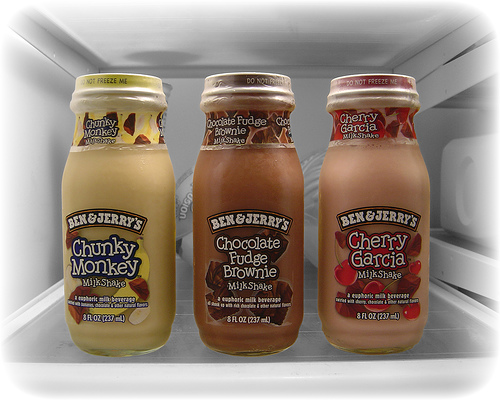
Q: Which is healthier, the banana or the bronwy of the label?
A: The banana is healthier than the brownie.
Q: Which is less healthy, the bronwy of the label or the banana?
A: The brownie is less healthy than the banana.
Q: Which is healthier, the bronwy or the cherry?
A: The cherry is healthier than the bronwy.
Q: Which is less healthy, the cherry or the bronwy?
A: The bronwy is less healthy than the cherry.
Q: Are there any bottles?
A: Yes, there is a bottle.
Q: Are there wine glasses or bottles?
A: Yes, there is a bottle.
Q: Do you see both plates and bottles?
A: No, there is a bottle but no plates.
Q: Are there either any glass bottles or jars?
A: Yes, there is a glass bottle.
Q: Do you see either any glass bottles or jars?
A: Yes, there is a glass bottle.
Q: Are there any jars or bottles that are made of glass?
A: Yes, the bottle is made of glass.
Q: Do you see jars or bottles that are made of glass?
A: Yes, the bottle is made of glass.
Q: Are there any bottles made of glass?
A: Yes, there is a bottle that is made of glass.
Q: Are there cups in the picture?
A: No, there are no cups.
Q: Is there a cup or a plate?
A: No, there are no cups or plates.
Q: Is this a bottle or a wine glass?
A: This is a bottle.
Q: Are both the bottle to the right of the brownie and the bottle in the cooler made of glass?
A: Yes, both the bottle and the bottle are made of glass.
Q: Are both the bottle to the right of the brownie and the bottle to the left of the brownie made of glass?
A: Yes, both the bottle and the bottle are made of glass.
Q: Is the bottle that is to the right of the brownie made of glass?
A: Yes, the bottle is made of glass.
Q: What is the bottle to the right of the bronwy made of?
A: The bottle is made of glass.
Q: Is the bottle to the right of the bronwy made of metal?
A: No, the bottle is made of glass.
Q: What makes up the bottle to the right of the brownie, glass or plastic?
A: The bottle is made of glass.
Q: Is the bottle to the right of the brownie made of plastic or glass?
A: The bottle is made of glass.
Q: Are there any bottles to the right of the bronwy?
A: Yes, there is a bottle to the right of the bronwy.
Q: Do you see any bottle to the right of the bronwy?
A: Yes, there is a bottle to the right of the bronwy.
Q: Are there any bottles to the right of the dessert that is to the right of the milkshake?
A: Yes, there is a bottle to the right of the bronwy.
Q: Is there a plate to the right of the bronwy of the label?
A: No, there is a bottle to the right of the brownie.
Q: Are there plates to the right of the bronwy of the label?
A: No, there is a bottle to the right of the brownie.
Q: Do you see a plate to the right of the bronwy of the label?
A: No, there is a bottle to the right of the brownie.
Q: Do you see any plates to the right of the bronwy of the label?
A: No, there is a bottle to the right of the brownie.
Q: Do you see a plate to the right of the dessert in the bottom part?
A: No, there is a bottle to the right of the brownie.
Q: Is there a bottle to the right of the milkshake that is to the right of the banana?
A: Yes, there is a bottle to the right of the milkshake.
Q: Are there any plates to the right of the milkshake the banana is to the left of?
A: No, there is a bottle to the right of the milkshake.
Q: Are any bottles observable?
A: Yes, there is a bottle.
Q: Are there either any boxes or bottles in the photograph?
A: Yes, there is a bottle.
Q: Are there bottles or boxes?
A: Yes, there is a bottle.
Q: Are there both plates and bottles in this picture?
A: No, there is a bottle but no plates.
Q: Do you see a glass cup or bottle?
A: Yes, there is a glass bottle.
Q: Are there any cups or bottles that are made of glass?
A: Yes, the bottle is made of glass.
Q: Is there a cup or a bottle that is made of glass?
A: Yes, the bottle is made of glass.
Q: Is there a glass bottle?
A: Yes, there is a bottle that is made of glass.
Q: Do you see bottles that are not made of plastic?
A: Yes, there is a bottle that is made of glass.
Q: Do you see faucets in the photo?
A: No, there are no faucets.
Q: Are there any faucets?
A: No, there are no faucets.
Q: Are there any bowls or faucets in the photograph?
A: No, there are no faucets or bowls.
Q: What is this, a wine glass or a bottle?
A: This is a bottle.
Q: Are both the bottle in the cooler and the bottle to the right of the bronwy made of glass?
A: Yes, both the bottle and the bottle are made of glass.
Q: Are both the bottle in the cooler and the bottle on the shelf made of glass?
A: Yes, both the bottle and the bottle are made of glass.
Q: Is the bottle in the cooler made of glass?
A: Yes, the bottle is made of glass.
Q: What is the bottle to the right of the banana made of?
A: The bottle is made of glass.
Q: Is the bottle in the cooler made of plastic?
A: No, the bottle is made of glass.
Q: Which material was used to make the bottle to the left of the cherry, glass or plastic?
A: The bottle is made of glass.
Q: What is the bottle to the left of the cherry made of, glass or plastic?
A: The bottle is made of glass.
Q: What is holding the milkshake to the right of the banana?
A: The bottle is holding the milkshake.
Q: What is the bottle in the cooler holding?
A: The bottle is holding the milkshake.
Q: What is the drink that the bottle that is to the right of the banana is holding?
A: The drink is a milkshake.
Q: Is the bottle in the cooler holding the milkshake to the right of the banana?
A: Yes, the bottle is holding the milkshake.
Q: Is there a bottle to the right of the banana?
A: Yes, there is a bottle to the right of the banana.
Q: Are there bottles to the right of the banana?
A: Yes, there is a bottle to the right of the banana.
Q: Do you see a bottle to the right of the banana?
A: Yes, there is a bottle to the right of the banana.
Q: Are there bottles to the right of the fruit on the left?
A: Yes, there is a bottle to the right of the banana.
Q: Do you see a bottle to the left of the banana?
A: No, the bottle is to the right of the banana.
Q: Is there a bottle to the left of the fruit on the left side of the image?
A: No, the bottle is to the right of the banana.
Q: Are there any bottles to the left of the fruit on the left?
A: No, the bottle is to the right of the banana.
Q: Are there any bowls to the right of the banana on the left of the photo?
A: No, there is a bottle to the right of the banana.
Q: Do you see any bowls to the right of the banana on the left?
A: No, there is a bottle to the right of the banana.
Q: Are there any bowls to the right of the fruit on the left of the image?
A: No, there is a bottle to the right of the banana.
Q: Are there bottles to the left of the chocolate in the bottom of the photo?
A: Yes, there is a bottle to the left of the chocolate.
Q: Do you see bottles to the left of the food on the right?
A: Yes, there is a bottle to the left of the chocolate.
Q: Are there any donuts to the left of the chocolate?
A: No, there is a bottle to the left of the chocolate.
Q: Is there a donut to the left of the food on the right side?
A: No, there is a bottle to the left of the chocolate.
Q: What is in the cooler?
A: The bottle is in the cooler.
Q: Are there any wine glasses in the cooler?
A: No, there is a bottle in the cooler.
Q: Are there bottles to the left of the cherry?
A: Yes, there is a bottle to the left of the cherry.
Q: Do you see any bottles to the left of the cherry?
A: Yes, there is a bottle to the left of the cherry.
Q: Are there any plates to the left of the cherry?
A: No, there is a bottle to the left of the cherry.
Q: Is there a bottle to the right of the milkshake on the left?
A: Yes, there is a bottle to the right of the milkshake.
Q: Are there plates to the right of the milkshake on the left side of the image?
A: No, there is a bottle to the right of the milkshake.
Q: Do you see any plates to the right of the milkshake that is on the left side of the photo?
A: No, there is a bottle to the right of the milkshake.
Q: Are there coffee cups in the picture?
A: No, there are no coffee cups.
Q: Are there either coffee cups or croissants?
A: No, there are no coffee cups or croissants.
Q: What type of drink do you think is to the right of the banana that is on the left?
A: The drink is a milkshake.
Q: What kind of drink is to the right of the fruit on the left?
A: The drink is a milkshake.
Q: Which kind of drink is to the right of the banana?
A: The drink is a milkshake.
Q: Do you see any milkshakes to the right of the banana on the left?
A: Yes, there is a milkshake to the right of the banana.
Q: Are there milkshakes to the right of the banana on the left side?
A: Yes, there is a milkshake to the right of the banana.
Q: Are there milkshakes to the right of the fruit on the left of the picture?
A: Yes, there is a milkshake to the right of the banana.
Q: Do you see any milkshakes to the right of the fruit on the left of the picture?
A: Yes, there is a milkshake to the right of the banana.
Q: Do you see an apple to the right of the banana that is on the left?
A: No, there is a milkshake to the right of the banana.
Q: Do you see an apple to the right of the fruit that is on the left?
A: No, there is a milkshake to the right of the banana.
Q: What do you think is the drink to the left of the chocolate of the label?
A: The drink is a milkshake.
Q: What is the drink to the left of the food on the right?
A: The drink is a milkshake.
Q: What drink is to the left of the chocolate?
A: The drink is a milkshake.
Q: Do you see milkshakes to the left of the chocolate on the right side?
A: Yes, there is a milkshake to the left of the chocolate.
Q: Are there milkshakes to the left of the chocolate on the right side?
A: Yes, there is a milkshake to the left of the chocolate.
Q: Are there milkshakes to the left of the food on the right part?
A: Yes, there is a milkshake to the left of the chocolate.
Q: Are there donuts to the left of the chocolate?
A: No, there is a milkshake to the left of the chocolate.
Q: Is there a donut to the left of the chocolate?
A: No, there is a milkshake to the left of the chocolate.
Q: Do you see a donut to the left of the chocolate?
A: No, there is a milkshake to the left of the chocolate.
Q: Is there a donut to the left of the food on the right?
A: No, there is a milkshake to the left of the chocolate.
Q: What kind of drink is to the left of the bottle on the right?
A: The drink is a milkshake.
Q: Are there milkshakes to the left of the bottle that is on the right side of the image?
A: Yes, there is a milkshake to the left of the bottle.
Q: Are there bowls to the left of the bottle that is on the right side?
A: No, there is a milkshake to the left of the bottle.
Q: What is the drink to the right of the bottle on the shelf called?
A: The drink is a milkshake.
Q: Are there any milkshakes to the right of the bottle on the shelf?
A: Yes, there is a milkshake to the right of the bottle.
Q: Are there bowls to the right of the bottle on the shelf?
A: No, there is a milkshake to the right of the bottle.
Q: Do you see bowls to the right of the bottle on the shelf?
A: No, there is a milkshake to the right of the bottle.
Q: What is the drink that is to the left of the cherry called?
A: The drink is a milkshake.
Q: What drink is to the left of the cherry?
A: The drink is a milkshake.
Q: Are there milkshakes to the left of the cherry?
A: Yes, there is a milkshake to the left of the cherry.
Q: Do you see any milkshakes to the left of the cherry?
A: Yes, there is a milkshake to the left of the cherry.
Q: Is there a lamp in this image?
A: No, there are no lamps.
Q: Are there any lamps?
A: No, there are no lamps.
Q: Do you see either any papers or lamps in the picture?
A: No, there are no lamps or papers.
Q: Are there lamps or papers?
A: No, there are no lamps or papers.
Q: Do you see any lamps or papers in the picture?
A: No, there are no lamps or papers.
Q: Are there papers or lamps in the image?
A: No, there are no lamps or papers.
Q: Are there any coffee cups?
A: No, there are no coffee cups.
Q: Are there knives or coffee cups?
A: No, there are no coffee cups or knives.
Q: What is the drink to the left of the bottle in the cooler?
A: The drink is a milkshake.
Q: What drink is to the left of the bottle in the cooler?
A: The drink is a milkshake.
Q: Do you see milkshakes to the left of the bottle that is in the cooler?
A: Yes, there is a milkshake to the left of the bottle.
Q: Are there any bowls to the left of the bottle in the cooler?
A: No, there is a milkshake to the left of the bottle.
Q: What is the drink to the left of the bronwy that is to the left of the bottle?
A: The drink is a milkshake.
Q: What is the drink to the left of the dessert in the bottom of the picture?
A: The drink is a milkshake.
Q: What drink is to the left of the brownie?
A: The drink is a milkshake.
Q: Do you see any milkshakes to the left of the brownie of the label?
A: Yes, there is a milkshake to the left of the bronwy.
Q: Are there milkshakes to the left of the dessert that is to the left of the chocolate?
A: Yes, there is a milkshake to the left of the bronwy.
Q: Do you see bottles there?
A: Yes, there is a bottle.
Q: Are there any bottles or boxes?
A: Yes, there is a bottle.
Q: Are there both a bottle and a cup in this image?
A: No, there is a bottle but no cups.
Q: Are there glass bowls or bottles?
A: Yes, there is a glass bottle.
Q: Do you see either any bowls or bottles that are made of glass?
A: Yes, the bottle is made of glass.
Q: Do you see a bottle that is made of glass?
A: Yes, there is a bottle that is made of glass.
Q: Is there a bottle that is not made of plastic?
A: Yes, there is a bottle that is made of glass.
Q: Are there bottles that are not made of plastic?
A: Yes, there is a bottle that is made of glass.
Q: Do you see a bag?
A: No, there are no bags.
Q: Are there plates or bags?
A: No, there are no bags or plates.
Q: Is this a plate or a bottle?
A: This is a bottle.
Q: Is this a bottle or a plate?
A: This is a bottle.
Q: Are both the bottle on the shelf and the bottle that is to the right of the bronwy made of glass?
A: Yes, both the bottle and the bottle are made of glass.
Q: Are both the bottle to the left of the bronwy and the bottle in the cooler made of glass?
A: Yes, both the bottle and the bottle are made of glass.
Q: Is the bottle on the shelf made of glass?
A: Yes, the bottle is made of glass.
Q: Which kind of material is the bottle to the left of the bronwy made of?
A: The bottle is made of glass.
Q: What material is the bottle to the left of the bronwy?
A: The bottle is made of glass.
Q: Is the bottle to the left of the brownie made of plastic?
A: No, the bottle is made of glass.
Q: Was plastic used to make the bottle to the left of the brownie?
A: No, the bottle is made of glass.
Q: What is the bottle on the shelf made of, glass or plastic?
A: The bottle is made of glass.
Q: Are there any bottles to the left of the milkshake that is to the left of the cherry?
A: Yes, there is a bottle to the left of the milkshake.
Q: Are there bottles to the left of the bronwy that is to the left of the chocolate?
A: Yes, there is a bottle to the left of the brownie.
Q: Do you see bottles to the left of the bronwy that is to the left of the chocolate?
A: Yes, there is a bottle to the left of the brownie.